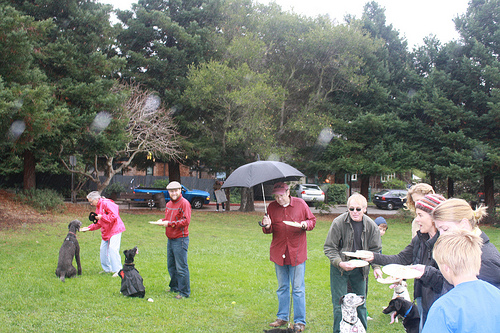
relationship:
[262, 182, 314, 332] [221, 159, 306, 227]
man holding black umbrella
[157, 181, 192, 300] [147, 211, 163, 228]
man holding plate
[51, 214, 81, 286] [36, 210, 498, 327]
dog in grass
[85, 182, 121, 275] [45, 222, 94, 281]
woman feeding dog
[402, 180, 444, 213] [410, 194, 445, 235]
hat on head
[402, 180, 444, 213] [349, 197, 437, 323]
hat on woman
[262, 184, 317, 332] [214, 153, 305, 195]
man under umbrella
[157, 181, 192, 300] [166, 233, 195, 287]
man wearing jeans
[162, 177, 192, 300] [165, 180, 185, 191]
man wearing hat